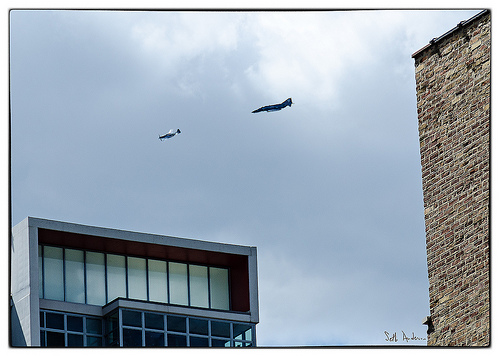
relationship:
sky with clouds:
[11, 11, 483, 345] [149, 11, 392, 101]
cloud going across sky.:
[105, 16, 386, 89] [59, 29, 226, 96]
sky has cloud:
[11, 11, 483, 345] [105, 16, 386, 89]